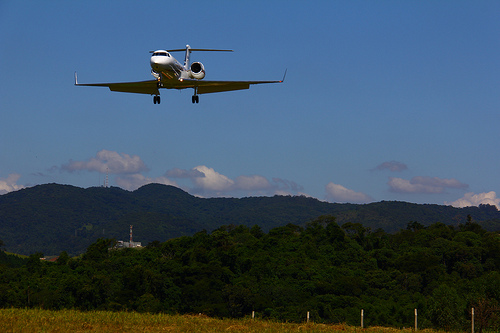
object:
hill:
[0, 181, 499, 260]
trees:
[0, 211, 499, 332]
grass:
[0, 305, 477, 332]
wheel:
[193, 94, 201, 105]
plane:
[71, 43, 289, 106]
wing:
[196, 66, 289, 95]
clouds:
[35, 150, 147, 177]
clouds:
[189, 163, 236, 192]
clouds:
[320, 180, 378, 204]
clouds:
[443, 191, 499, 211]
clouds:
[237, 174, 307, 197]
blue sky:
[0, 0, 499, 211]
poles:
[468, 305, 476, 333]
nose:
[150, 53, 175, 64]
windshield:
[150, 51, 172, 58]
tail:
[146, 43, 238, 52]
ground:
[0, 304, 445, 333]